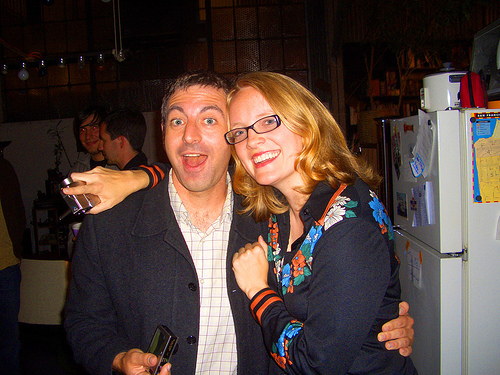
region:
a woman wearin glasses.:
[218, 111, 283, 154]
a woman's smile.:
[247, 146, 289, 173]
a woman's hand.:
[230, 234, 276, 304]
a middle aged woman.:
[218, 62, 415, 374]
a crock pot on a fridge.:
[417, 58, 476, 115]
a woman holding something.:
[61, 166, 151, 219]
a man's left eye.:
[198, 101, 228, 131]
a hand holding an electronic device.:
[110, 324, 188, 374]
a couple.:
[57, 69, 417, 374]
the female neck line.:
[268, 167, 313, 228]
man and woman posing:
[60, 68, 419, 370]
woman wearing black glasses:
[218, 71, 352, 192]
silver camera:
[49, 172, 101, 223]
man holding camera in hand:
[53, 67, 261, 374]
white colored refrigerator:
[376, 106, 499, 373]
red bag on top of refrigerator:
[455, 66, 489, 116]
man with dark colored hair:
[154, 71, 236, 203]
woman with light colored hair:
[218, 69, 389, 224]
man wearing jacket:
[60, 71, 285, 374]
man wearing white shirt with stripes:
[53, 66, 240, 374]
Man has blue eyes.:
[151, 103, 228, 134]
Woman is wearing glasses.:
[221, 111, 284, 145]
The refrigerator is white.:
[388, 117, 499, 355]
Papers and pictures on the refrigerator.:
[383, 121, 443, 241]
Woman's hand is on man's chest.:
[218, 222, 275, 317]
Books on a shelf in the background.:
[351, 47, 431, 112]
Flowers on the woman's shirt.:
[275, 197, 397, 284]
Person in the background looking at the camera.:
[58, 105, 110, 155]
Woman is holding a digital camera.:
[40, 152, 105, 217]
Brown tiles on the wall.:
[213, 2, 289, 63]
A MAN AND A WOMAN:
[50, 58, 438, 373]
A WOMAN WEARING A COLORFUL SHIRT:
[216, 65, 433, 369]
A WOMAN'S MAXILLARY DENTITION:
[244, 146, 286, 167]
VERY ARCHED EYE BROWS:
[155, 95, 228, 130]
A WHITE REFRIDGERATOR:
[366, 95, 498, 373]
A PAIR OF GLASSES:
[218, 111, 288, 147]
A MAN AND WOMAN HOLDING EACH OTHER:
[52, 55, 441, 373]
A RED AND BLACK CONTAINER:
[454, 63, 489, 118]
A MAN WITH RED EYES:
[64, 99, 131, 193]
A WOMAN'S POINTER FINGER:
[60, 175, 100, 200]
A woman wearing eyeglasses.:
[203, 91, 300, 156]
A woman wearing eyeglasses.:
[247, 93, 317, 182]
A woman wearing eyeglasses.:
[224, 83, 338, 247]